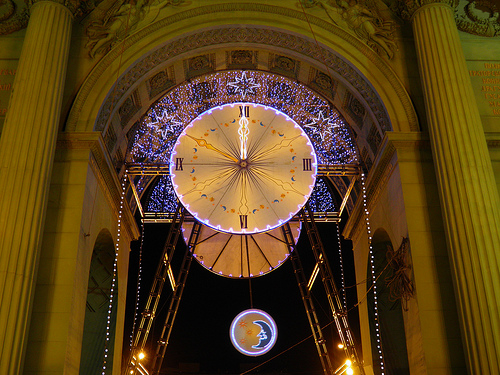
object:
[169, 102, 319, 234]
clock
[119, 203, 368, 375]
scaffolding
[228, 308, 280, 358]
sun and moon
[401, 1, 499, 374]
pillar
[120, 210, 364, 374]
sky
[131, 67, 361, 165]
display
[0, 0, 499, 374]
building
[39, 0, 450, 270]
wall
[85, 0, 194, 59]
statue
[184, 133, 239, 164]
hand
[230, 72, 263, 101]
star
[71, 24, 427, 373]
archway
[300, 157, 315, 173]
3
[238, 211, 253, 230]
6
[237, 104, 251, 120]
12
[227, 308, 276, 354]
crescent